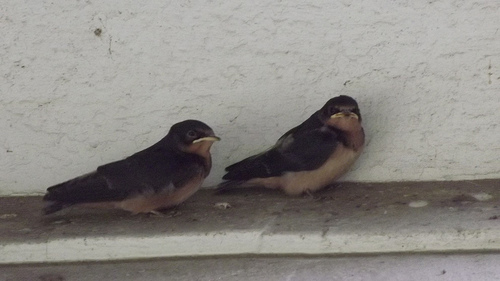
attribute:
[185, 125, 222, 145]
beak — gray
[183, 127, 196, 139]
eye — black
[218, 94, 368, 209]
bird — standing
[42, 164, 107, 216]
tail — long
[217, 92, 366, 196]
bird — standing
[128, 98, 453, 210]
bird — standing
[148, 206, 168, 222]
legs — short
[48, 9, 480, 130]
wall — white, gray, concrete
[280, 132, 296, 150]
feathers — black, brown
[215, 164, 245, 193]
feathers — black, brown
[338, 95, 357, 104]
feathers — black, brown